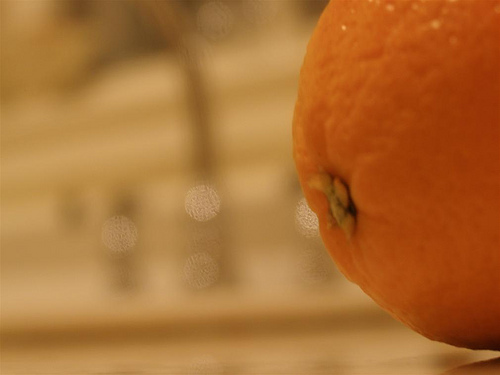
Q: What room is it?
A: It is a kitchen.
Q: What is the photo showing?
A: It is showing a kitchen.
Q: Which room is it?
A: It is a kitchen.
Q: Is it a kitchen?
A: Yes, it is a kitchen.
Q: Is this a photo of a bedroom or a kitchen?
A: It is showing a kitchen.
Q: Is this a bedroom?
A: No, it is a kitchen.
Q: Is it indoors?
A: Yes, it is indoors.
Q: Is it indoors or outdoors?
A: It is indoors.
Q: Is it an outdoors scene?
A: No, it is indoors.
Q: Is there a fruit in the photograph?
A: Yes, there is a fruit.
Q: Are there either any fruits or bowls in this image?
A: Yes, there is a fruit.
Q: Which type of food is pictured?
A: The food is a fruit.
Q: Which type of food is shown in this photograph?
A: The food is a fruit.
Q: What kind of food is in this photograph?
A: The food is a fruit.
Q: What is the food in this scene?
A: The food is a fruit.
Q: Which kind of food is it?
A: The food is a fruit.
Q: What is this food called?
A: This is a fruit.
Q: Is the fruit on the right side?
A: Yes, the fruit is on the right of the image.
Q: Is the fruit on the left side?
A: No, the fruit is on the right of the image.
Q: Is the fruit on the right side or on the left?
A: The fruit is on the right of the image.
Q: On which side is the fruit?
A: The fruit is on the right of the image.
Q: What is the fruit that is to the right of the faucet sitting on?
A: The fruit is sitting on the counter.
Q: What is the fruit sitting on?
A: The fruit is sitting on the counter.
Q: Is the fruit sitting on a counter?
A: Yes, the fruit is sitting on a counter.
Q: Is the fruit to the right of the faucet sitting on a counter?
A: Yes, the fruit is sitting on a counter.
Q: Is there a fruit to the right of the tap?
A: Yes, there is a fruit to the right of the tap.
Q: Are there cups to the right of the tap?
A: No, there is a fruit to the right of the tap.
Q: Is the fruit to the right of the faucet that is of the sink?
A: Yes, the fruit is to the right of the tap.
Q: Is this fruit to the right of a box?
A: No, the fruit is to the right of the tap.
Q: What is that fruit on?
A: The fruit is on the table.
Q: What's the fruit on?
A: The fruit is on the table.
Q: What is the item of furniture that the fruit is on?
A: The piece of furniture is a table.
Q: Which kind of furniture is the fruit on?
A: The fruit is on the table.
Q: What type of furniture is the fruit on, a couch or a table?
A: The fruit is on a table.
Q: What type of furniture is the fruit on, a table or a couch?
A: The fruit is on a table.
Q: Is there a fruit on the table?
A: Yes, there is a fruit on the table.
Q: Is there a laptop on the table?
A: No, there is a fruit on the table.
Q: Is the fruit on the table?
A: Yes, the fruit is on the table.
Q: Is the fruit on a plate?
A: No, the fruit is on the table.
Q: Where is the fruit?
A: The fruit is in the kitchen.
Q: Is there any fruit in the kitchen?
A: Yes, there is a fruit in the kitchen.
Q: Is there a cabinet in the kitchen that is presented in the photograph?
A: No, there is a fruit in the kitchen.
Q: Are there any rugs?
A: No, there are no rugs.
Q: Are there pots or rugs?
A: No, there are no rugs or pots.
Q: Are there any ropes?
A: No, there are no ropes.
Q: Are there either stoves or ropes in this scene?
A: No, there are no ropes or stoves.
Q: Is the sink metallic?
A: Yes, the sink is metallic.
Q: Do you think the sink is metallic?
A: Yes, the sink is metallic.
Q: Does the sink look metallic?
A: Yes, the sink is metallic.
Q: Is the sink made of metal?
A: Yes, the sink is made of metal.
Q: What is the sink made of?
A: The sink is made of metal.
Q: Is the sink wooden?
A: No, the sink is metallic.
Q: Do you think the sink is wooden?
A: No, the sink is metallic.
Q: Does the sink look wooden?
A: No, the sink is metallic.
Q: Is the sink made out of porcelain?
A: No, the sink is made of metal.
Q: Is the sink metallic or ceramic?
A: The sink is metallic.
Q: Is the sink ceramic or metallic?
A: The sink is metallic.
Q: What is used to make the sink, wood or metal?
A: The sink is made of metal.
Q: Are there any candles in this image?
A: No, there are no candles.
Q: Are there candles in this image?
A: No, there are no candles.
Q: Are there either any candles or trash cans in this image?
A: No, there are no candles or trash cans.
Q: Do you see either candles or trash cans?
A: No, there are no candles or trash cans.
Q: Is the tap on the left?
A: Yes, the tap is on the left of the image.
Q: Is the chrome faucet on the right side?
A: No, the tap is on the left of the image.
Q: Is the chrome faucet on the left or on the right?
A: The faucet is on the left of the image.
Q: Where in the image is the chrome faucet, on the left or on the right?
A: The faucet is on the left of the image.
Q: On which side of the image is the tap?
A: The tap is on the left of the image.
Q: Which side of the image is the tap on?
A: The tap is on the left of the image.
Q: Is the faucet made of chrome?
A: Yes, the faucet is made of chrome.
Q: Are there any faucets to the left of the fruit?
A: Yes, there is a faucet to the left of the fruit.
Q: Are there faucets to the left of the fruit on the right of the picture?
A: Yes, there is a faucet to the left of the fruit.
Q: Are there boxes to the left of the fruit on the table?
A: No, there is a faucet to the left of the fruit.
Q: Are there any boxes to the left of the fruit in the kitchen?
A: No, there is a faucet to the left of the fruit.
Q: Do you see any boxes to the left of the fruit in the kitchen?
A: No, there is a faucet to the left of the fruit.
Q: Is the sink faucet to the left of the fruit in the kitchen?
A: Yes, the tap is to the left of the fruit.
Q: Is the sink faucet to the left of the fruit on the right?
A: Yes, the tap is to the left of the fruit.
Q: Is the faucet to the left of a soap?
A: No, the faucet is to the left of the fruit.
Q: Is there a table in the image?
A: Yes, there is a table.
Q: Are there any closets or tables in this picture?
A: Yes, there is a table.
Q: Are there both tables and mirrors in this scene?
A: No, there is a table but no mirrors.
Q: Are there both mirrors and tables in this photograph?
A: No, there is a table but no mirrors.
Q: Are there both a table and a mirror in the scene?
A: No, there is a table but no mirrors.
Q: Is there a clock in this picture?
A: No, there are no clocks.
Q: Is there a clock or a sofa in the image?
A: No, there are no clocks or sofas.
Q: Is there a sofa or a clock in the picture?
A: No, there are no clocks or sofas.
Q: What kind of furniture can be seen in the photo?
A: The furniture is a table.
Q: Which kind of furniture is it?
A: The piece of furniture is a table.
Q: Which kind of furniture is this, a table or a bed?
A: That is a table.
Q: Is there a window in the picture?
A: Yes, there is a window.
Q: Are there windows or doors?
A: Yes, there is a window.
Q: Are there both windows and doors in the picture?
A: No, there is a window but no doors.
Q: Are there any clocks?
A: No, there are no clocks.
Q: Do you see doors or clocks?
A: No, there are no clocks or doors.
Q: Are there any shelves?
A: No, there are no shelves.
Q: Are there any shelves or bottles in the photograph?
A: No, there are no shelves or bottles.